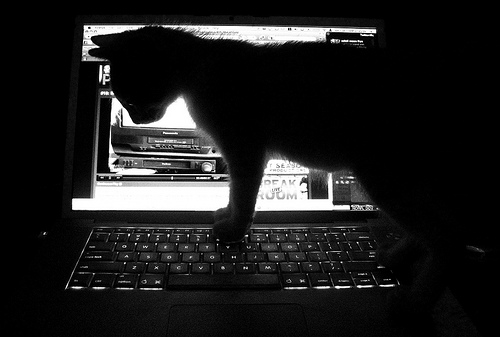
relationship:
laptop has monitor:
[46, 16, 424, 330] [64, 10, 398, 223]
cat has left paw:
[87, 19, 497, 268] [211, 215, 258, 246]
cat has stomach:
[87, 19, 497, 268] [267, 142, 359, 177]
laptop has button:
[46, 16, 424, 330] [345, 246, 387, 264]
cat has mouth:
[87, 19, 497, 268] [125, 110, 167, 131]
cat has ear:
[87, 19, 497, 268] [86, 48, 106, 59]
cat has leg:
[87, 19, 497, 268] [218, 144, 273, 220]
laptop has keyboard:
[46, 16, 424, 330] [64, 220, 404, 300]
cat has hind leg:
[87, 19, 497, 268] [351, 172, 471, 298]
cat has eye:
[87, 19, 497, 268] [124, 101, 137, 107]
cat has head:
[87, 19, 497, 268] [85, 19, 186, 127]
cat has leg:
[87, 19, 497, 268] [361, 171, 435, 240]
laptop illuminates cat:
[46, 16, 424, 330] [87, 19, 497, 268]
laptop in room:
[46, 16, 424, 330] [2, 2, 500, 335]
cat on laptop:
[87, 19, 497, 268] [46, 16, 424, 330]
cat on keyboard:
[87, 19, 497, 268] [64, 220, 404, 300]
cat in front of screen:
[87, 19, 497, 268] [67, 14, 393, 223]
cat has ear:
[87, 19, 497, 268] [86, 48, 114, 60]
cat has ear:
[87, 19, 497, 268] [90, 32, 117, 47]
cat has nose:
[87, 19, 497, 268] [128, 118, 142, 126]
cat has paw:
[87, 19, 497, 268] [211, 215, 258, 246]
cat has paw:
[87, 19, 497, 268] [209, 202, 234, 220]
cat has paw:
[87, 19, 497, 268] [371, 243, 408, 270]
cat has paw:
[87, 19, 497, 268] [400, 273, 439, 304]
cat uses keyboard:
[87, 19, 497, 268] [64, 220, 404, 300]